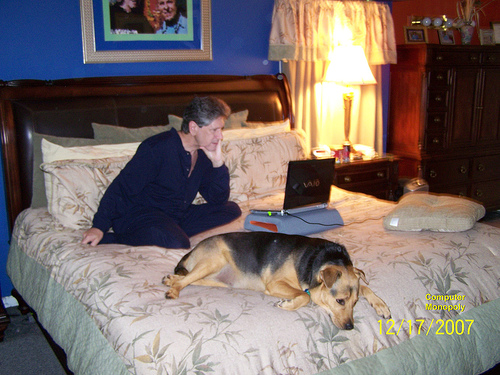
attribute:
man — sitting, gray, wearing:
[81, 91, 248, 251]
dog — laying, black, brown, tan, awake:
[166, 224, 397, 333]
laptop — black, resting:
[252, 156, 333, 216]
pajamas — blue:
[84, 129, 227, 219]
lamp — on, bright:
[322, 42, 380, 157]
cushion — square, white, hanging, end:
[387, 190, 489, 235]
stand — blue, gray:
[247, 212, 345, 234]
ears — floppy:
[320, 264, 372, 288]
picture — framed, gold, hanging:
[76, 0, 216, 61]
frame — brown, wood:
[2, 76, 293, 219]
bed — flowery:
[11, 174, 497, 374]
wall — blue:
[2, 2, 275, 84]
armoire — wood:
[396, 39, 496, 227]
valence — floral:
[15, 195, 497, 361]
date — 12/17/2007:
[376, 313, 479, 344]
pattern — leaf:
[137, 333, 174, 368]